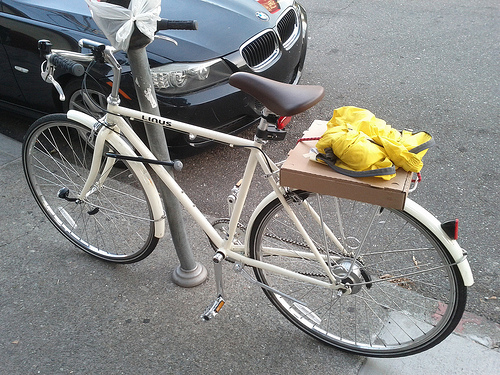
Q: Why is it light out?
A: Sunshine.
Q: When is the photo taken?
A: Daytime.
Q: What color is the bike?
A: White.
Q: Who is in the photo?
A: No one.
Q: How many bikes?
A: One.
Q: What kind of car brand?
A: BMW.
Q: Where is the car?
A: Street.